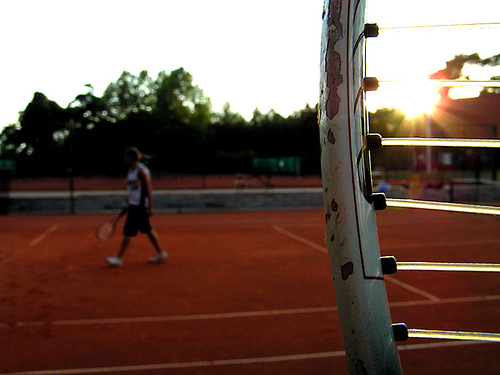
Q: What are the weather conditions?
A: It is clear.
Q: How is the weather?
A: It is clear.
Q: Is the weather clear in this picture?
A: Yes, it is clear.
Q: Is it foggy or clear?
A: It is clear.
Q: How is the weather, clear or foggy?
A: It is clear.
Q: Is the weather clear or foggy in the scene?
A: It is clear.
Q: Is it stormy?
A: No, it is clear.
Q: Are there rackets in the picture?
A: Yes, there is a racket.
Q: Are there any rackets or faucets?
A: Yes, there is a racket.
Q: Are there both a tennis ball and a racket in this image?
A: No, there is a racket but no tennis balls.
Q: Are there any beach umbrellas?
A: No, there are no beach umbrellas.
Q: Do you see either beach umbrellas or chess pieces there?
A: No, there are no beach umbrellas or chess pieces.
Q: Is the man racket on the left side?
A: Yes, the racket is on the left of the image.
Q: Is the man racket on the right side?
A: No, the racket is on the left of the image.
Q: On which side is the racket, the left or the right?
A: The racket is on the left of the image.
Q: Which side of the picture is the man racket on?
A: The tennis racket is on the left of the image.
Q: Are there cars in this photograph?
A: No, there are no cars.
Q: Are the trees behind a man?
A: Yes, the trees are behind a man.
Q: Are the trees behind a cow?
A: No, the trees are behind a man.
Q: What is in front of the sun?
A: The trees are in front of the sun.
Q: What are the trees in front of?
A: The trees are in front of the sun.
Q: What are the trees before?
A: The trees are in front of the sun.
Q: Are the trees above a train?
A: No, the trees are above a man.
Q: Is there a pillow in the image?
A: No, there are no pillows.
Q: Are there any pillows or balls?
A: No, there are no pillows or balls.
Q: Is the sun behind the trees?
A: Yes, the sun is behind the trees.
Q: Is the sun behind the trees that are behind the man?
A: Yes, the sun is behind the trees.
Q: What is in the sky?
A: The sun is in the sky.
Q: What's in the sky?
A: The sun is in the sky.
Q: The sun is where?
A: The sun is in the sky.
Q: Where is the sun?
A: The sun is in the sky.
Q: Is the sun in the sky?
A: Yes, the sun is in the sky.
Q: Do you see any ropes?
A: No, there are no ropes.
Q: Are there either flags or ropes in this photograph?
A: No, there are no ropes or flags.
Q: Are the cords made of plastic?
A: Yes, the cords are made of plastic.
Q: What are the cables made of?
A: The cables are made of plastic.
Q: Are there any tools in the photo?
A: No, there are no tools.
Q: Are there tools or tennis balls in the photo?
A: No, there are no tools or tennis balls.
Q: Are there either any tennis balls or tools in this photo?
A: No, there are no tools or tennis balls.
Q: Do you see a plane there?
A: No, there are no airplanes.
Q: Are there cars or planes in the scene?
A: No, there are no planes or cars.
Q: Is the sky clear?
A: Yes, the sky is clear.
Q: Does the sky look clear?
A: Yes, the sky is clear.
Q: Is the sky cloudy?
A: No, the sky is clear.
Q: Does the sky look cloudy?
A: No, the sky is clear.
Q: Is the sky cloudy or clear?
A: The sky is clear.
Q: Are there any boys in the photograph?
A: No, there are no boys.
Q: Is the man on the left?
A: Yes, the man is on the left of the image.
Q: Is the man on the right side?
A: No, the man is on the left of the image.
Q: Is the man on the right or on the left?
A: The man is on the left of the image.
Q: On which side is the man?
A: The man is on the left of the image.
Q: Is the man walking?
A: Yes, the man is walking.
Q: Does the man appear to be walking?
A: Yes, the man is walking.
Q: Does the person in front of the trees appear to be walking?
A: Yes, the man is walking.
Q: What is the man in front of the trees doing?
A: The man is walking.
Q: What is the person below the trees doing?
A: The man is walking.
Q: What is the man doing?
A: The man is walking.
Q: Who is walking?
A: The man is walking.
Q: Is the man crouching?
A: No, the man is walking.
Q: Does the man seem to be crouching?
A: No, the man is walking.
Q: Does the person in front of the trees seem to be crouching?
A: No, the man is walking.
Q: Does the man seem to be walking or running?
A: The man is walking.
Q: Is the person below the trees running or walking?
A: The man is walking.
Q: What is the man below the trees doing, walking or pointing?
A: The man is walking.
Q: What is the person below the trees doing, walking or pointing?
A: The man is walking.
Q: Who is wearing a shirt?
A: The man is wearing a shirt.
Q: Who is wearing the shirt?
A: The man is wearing a shirt.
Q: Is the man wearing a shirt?
A: Yes, the man is wearing a shirt.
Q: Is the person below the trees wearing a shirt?
A: Yes, the man is wearing a shirt.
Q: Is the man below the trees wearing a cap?
A: No, the man is wearing a shirt.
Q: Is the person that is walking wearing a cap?
A: No, the man is wearing a shirt.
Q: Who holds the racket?
A: The man holds the tennis racket.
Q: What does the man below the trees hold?
A: The man holds the racket.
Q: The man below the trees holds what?
A: The man holds the racket.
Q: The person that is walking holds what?
A: The man holds the racket.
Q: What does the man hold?
A: The man holds the racket.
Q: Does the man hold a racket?
A: Yes, the man holds a racket.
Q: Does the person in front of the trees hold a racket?
A: Yes, the man holds a racket.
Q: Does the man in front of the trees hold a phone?
A: No, the man holds a racket.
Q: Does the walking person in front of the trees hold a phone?
A: No, the man holds a racket.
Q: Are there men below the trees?
A: Yes, there is a man below the trees.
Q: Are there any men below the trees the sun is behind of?
A: Yes, there is a man below the trees.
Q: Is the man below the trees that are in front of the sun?
A: Yes, the man is below the trees.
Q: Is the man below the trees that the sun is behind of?
A: Yes, the man is below the trees.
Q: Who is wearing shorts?
A: The man is wearing shorts.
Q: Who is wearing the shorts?
A: The man is wearing shorts.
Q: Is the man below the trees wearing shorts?
A: Yes, the man is wearing shorts.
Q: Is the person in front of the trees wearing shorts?
A: Yes, the man is wearing shorts.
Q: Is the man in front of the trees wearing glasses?
A: No, the man is wearing shorts.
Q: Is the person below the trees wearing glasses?
A: No, the man is wearing shorts.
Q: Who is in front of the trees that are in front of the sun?
A: The man is in front of the trees.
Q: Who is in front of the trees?
A: The man is in front of the trees.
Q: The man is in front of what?
A: The man is in front of the trees.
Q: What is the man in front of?
A: The man is in front of the trees.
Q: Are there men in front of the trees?
A: Yes, there is a man in front of the trees.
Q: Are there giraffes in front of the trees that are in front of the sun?
A: No, there is a man in front of the trees.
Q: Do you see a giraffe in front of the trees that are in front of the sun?
A: No, there is a man in front of the trees.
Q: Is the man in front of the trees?
A: Yes, the man is in front of the trees.